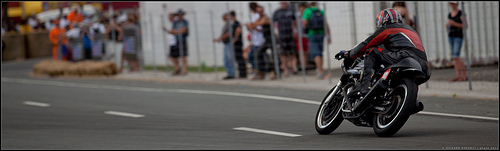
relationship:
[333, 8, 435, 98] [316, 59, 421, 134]
biker riding motorcycle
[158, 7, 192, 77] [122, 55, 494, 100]
people standing on sidewalk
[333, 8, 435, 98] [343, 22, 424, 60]
biker wearing jacket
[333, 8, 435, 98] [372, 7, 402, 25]
biker wearing helmet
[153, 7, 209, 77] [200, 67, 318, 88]
people standing on sidewalk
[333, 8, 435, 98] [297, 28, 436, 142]
biker riding a motorcycle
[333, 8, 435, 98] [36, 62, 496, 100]
biker watching from sidewalk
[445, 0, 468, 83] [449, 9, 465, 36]
woman wearing a shirt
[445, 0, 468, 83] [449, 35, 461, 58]
woman wearing a jeans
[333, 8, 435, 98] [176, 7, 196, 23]
biker wearing a hat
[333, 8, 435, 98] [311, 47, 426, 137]
biker riding a motorcycle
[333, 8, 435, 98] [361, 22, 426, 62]
biker riding a clothing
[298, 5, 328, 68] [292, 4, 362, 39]
man wearing a backpack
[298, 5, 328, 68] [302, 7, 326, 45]
man wearing a shirt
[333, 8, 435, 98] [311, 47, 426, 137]
biker steering their motorcycle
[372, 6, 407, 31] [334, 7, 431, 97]
helmet on rider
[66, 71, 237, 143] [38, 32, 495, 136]
lines on road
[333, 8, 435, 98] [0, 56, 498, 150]
biker waiting along ground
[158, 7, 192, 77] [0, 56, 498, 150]
people waiting along ground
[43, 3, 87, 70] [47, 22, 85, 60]
men in orange suits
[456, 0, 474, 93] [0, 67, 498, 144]
pole in ground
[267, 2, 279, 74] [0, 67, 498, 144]
pole in ground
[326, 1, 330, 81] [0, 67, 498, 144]
pole in ground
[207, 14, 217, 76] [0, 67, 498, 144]
pole in ground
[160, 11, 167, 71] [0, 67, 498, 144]
pole in ground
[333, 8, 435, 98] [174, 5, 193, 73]
biker standing next person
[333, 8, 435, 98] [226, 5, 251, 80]
biker standing next person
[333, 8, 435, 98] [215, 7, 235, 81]
biker standing next person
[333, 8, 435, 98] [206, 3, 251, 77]
biker standing next person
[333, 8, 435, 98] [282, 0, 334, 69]
biker standing next person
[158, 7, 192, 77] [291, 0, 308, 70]
people standing next person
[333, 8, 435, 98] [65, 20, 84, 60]
biker standing next person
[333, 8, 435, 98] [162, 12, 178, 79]
biker standing next person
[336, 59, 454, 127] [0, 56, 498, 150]
biker in middle of ground